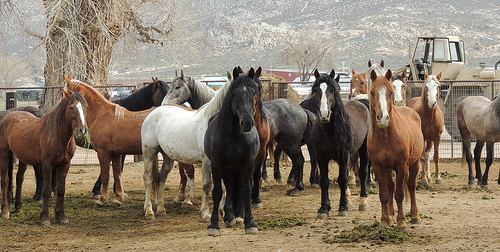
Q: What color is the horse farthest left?
A: Brown.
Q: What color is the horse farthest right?
A: Grey.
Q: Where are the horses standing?
A: Dirt.